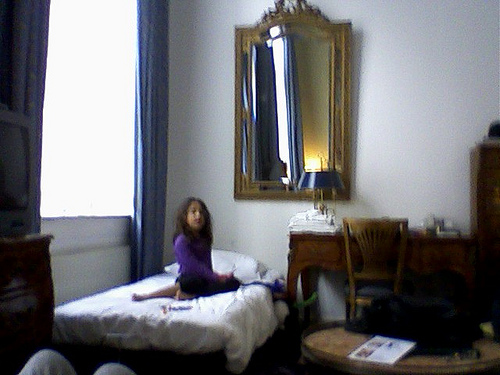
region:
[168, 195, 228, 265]
Person has dark hair.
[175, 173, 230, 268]
Person has long hair.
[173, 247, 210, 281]
Person wearing purple shirt.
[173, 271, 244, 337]
Person wearing dark pants.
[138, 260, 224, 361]
Person sitting on bed.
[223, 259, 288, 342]
White pillow on bed.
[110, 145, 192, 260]
Blue curtains hanging over window.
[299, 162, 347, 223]
Blue lampshade on lamp.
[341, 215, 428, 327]
Brown wood chair at desk.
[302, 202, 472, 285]
Wood desk near wall.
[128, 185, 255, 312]
Little girl sitting on a bed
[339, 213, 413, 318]
Wooden desk chair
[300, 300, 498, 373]
Small table in the center of room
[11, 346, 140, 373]
Knees of the photographer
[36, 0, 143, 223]
Very large window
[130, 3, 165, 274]
Blue drapes hung on window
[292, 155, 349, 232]
Table lamp sitting on a desk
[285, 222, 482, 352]
Antique desk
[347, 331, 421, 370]
Reading material sitting on the table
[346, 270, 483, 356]
Backpack sitting on the table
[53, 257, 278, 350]
A small, white bed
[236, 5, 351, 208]
A large mirror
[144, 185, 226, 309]
A child on the bed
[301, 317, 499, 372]
A wooden table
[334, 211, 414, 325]
A wooden chair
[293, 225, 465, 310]
A wooden desk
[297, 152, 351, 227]
A blue and gold lamp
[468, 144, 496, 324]
A wooden dresser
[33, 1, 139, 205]
A window next to the bed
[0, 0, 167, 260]
Blue curtains next to the window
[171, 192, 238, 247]
Girl sitting on top of bed.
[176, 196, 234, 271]
Girl has long hair.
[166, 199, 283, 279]
Girl has dark hair.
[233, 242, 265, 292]
White pillow on bed.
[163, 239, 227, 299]
Girl wearing purple shirt.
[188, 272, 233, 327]
Girl is wearing black pants.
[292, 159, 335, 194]
Blue lamp shade on lamp.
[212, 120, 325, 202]
Large mirror behind girl.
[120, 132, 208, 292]
Long blue curtains over window.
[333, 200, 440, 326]
Brown wood chair near desk.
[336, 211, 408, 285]
A brown studying chair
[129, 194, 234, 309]
Little girl sitted on bed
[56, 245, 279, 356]
A well spread bed in white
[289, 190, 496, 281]
Reading table at a corner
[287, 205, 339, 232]
A pile of books on the table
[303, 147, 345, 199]
A bedside lamb with a nevy blue stand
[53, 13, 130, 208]
window of the room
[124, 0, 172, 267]
Blue curtain hanging on the wall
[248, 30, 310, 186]
Reflection of the window on a mirror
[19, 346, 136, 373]
knees of a person seated